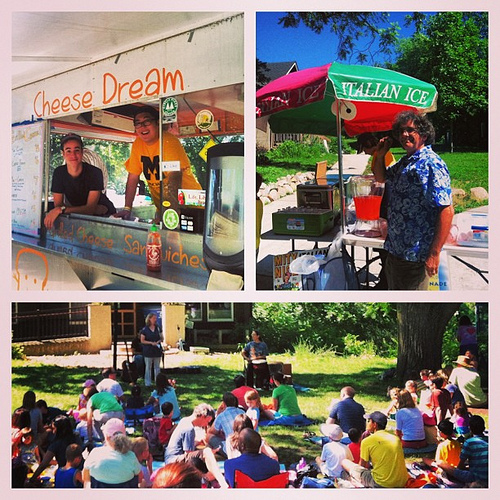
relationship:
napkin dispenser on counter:
[205, 145, 248, 294] [12, 232, 214, 287]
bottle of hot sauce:
[147, 225, 166, 280] [144, 232, 162, 273]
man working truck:
[43, 131, 117, 231] [16, 10, 246, 294]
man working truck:
[111, 104, 205, 226] [16, 10, 246, 294]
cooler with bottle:
[271, 202, 336, 236] [275, 206, 281, 212]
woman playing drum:
[241, 330, 271, 391] [253, 356, 268, 381]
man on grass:
[339, 409, 410, 487] [256, 145, 500, 208]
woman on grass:
[273, 373, 299, 418] [9, 352, 487, 488]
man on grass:
[83, 415, 145, 491] [9, 352, 487, 488]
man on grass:
[224, 429, 280, 485] [9, 352, 487, 488]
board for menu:
[6, 119, 50, 236] [13, 123, 43, 229]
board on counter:
[6, 119, 50, 236] [12, 232, 214, 287]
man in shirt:
[339, 409, 410, 487] [359, 429, 408, 488]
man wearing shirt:
[379, 109, 455, 291] [378, 143, 450, 264]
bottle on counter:
[147, 225, 166, 280] [12, 232, 214, 287]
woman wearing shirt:
[273, 373, 299, 418] [269, 382, 298, 416]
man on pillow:
[224, 429, 280, 485] [402, 472, 436, 490]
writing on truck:
[9, 66, 209, 296] [16, 10, 246, 294]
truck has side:
[16, 10, 246, 294] [12, 12, 243, 289]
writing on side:
[9, 66, 209, 296] [12, 12, 243, 289]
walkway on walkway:
[255, 232, 489, 290] [257, 234, 488, 293]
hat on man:
[100, 417, 125, 446] [83, 415, 145, 491]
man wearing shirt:
[111, 104, 205, 226] [121, 127, 204, 201]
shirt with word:
[121, 127, 204, 201] [136, 152, 169, 185]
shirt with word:
[121, 127, 204, 201] [145, 178, 160, 186]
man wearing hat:
[43, 131, 117, 231] [63, 127, 85, 142]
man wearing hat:
[136, 309, 165, 388] [144, 309, 156, 323]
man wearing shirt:
[38, 127, 116, 235] [47, 158, 109, 215]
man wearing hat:
[38, 127, 116, 235] [53, 130, 83, 152]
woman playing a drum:
[237, 327, 273, 387] [248, 357, 270, 383]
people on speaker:
[150, 458, 202, 488] [204, 323, 311, 393]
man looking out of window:
[43, 131, 117, 231] [49, 109, 161, 225]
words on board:
[14, 129, 41, 186] [9, 119, 50, 235]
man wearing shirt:
[113, 107, 203, 228] [123, 129, 205, 213]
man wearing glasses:
[113, 107, 203, 228] [134, 119, 153, 129]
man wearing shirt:
[379, 109, 455, 291] [380, 147, 456, 270]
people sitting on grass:
[12, 338, 488, 488] [13, 352, 488, 487]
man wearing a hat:
[359, 413, 409, 484] [358, 405, 398, 424]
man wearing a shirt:
[359, 413, 409, 484] [367, 428, 407, 478]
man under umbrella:
[361, 114, 458, 294] [255, 36, 440, 147]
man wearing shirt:
[379, 109, 455, 291] [388, 141, 455, 253]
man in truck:
[43, 131, 117, 231] [16, 10, 246, 294]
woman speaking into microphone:
[124, 310, 175, 399] [153, 325, 162, 336]